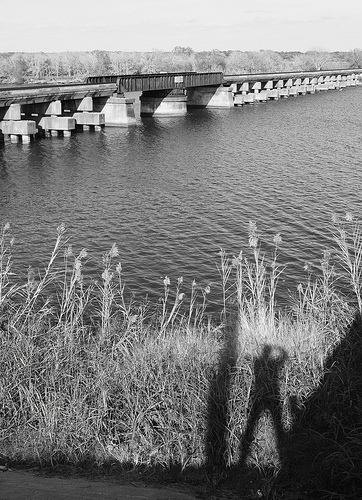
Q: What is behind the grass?
A: Body of water.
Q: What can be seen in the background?
A: Trees.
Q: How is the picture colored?
A: Black and white.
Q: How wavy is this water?
A: Slightly.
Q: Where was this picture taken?
A: By a bridge.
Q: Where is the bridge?
A: Above the water.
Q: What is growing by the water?
A: Grass.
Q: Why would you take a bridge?
A: To travel over something.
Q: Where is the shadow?
A: Bottom right.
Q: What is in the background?
A: Trees.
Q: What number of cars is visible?
A: 0.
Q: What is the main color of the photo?
A: Black and white.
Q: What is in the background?
A: Trees.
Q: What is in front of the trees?
A: Bridge.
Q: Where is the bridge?
A: Over the water.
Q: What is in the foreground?
A: Weeds.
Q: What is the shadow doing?
A: Taking a picture.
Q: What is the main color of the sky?
A: White.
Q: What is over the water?
A: A bridge.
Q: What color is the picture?
A: Black and white.